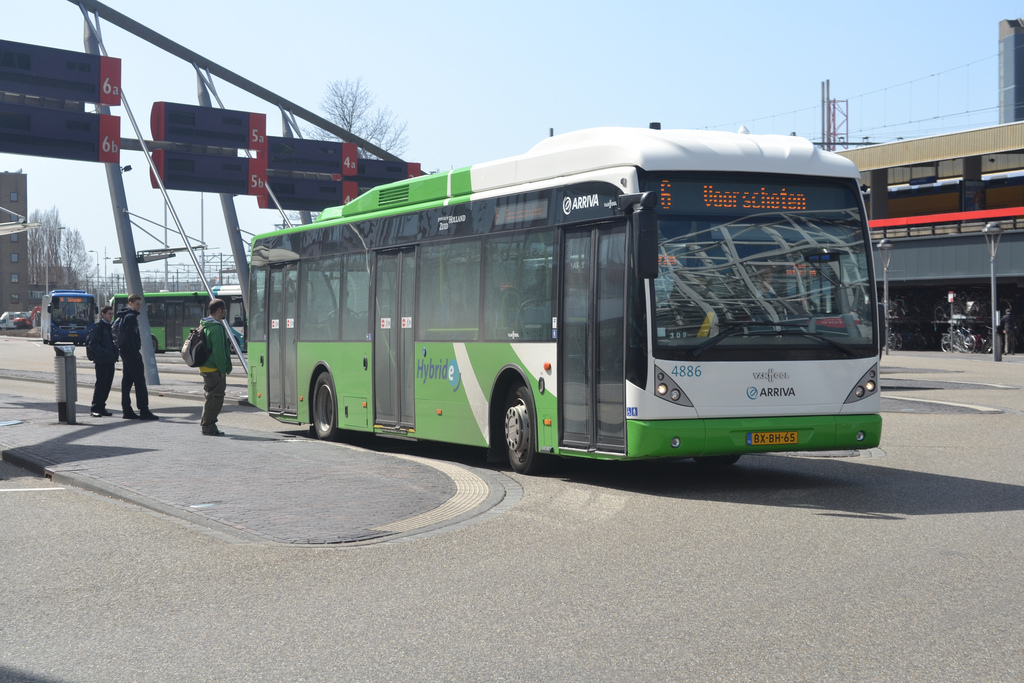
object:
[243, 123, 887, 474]
bus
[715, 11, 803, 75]
sky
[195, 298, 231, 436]
man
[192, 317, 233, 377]
jacket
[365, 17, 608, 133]
clouds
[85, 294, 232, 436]
group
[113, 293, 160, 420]
person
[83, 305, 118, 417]
person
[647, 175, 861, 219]
display